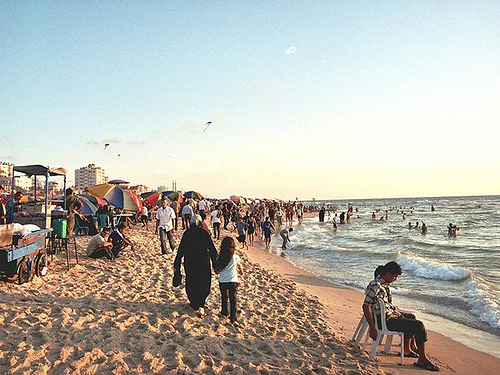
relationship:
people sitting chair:
[360, 261, 443, 372] [364, 297, 406, 358]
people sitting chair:
[360, 261, 443, 372] [352, 287, 382, 344]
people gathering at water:
[0, 185, 460, 372] [267, 192, 499, 359]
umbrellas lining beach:
[0, 180, 280, 207] [3, 185, 487, 367]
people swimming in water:
[318, 203, 460, 237] [281, 190, 498, 337]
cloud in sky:
[275, 36, 299, 58] [20, 24, 482, 169]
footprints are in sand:
[104, 215, 325, 371] [31, 200, 315, 372]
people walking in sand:
[146, 197, 288, 259] [177, 296, 253, 333]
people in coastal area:
[105, 135, 262, 291] [292, 225, 357, 300]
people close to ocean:
[181, 179, 291, 258] [316, 158, 496, 306]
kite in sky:
[203, 121, 211, 132] [3, 2, 498, 198]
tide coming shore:
[264, 197, 498, 335] [260, 256, 349, 320]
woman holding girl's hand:
[169, 218, 219, 315] [213, 261, 219, 278]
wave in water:
[395, 256, 498, 329] [353, 202, 498, 255]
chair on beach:
[352, 298, 405, 364] [3, 185, 487, 367]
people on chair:
[360, 261, 443, 372] [352, 298, 405, 364]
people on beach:
[360, 261, 443, 372] [3, 185, 487, 367]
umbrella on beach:
[96, 186, 148, 218] [3, 170, 490, 374]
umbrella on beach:
[186, 188, 204, 202] [3, 170, 490, 374]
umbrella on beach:
[148, 188, 163, 203] [3, 170, 490, 374]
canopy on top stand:
[14, 159, 69, 181] [16, 200, 67, 230]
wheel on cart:
[18, 258, 32, 284] [0, 229, 55, 278]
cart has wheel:
[0, 229, 55, 278] [18, 258, 32, 284]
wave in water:
[386, 235, 498, 329] [291, 202, 484, 265]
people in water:
[318, 201, 465, 237] [276, 196, 498, 326]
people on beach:
[172, 213, 243, 326] [227, 217, 364, 366]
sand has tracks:
[2, 218, 494, 374] [0, 226, 385, 373]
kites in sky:
[98, 115, 217, 152] [38, 25, 460, 164]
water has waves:
[400, 231, 480, 308] [400, 251, 483, 311]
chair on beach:
[348, 293, 422, 365] [3, 185, 487, 367]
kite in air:
[201, 120, 215, 132] [5, 7, 489, 367]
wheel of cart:
[14, 258, 34, 281] [1, 210, 53, 295]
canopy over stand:
[13, 164, 67, 176] [7, 202, 55, 230]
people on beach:
[360, 257, 442, 365] [64, 277, 328, 374]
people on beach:
[260, 214, 273, 241] [64, 277, 328, 374]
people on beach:
[159, 199, 177, 254] [64, 277, 328, 374]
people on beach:
[87, 225, 112, 260] [64, 277, 328, 374]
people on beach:
[240, 212, 247, 247] [64, 277, 328, 374]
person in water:
[449, 224, 453, 239] [303, 201, 483, 274]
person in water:
[419, 224, 426, 236] [303, 201, 483, 274]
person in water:
[430, 204, 435, 213] [303, 201, 483, 274]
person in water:
[319, 209, 324, 223] [303, 201, 483, 274]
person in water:
[344, 212, 351, 225] [303, 201, 483, 274]